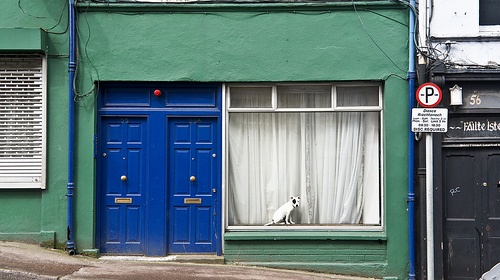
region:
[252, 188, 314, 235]
a dog with one brown eye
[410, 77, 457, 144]
a pair of traffic signs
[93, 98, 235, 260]
a pair of blue doors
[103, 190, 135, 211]
a gold mail slot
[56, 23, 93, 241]
a blue metal pole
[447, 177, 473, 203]
a small patch of grafiti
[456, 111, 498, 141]
a painted on sign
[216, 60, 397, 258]
a large square window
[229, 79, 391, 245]
a set of white curtains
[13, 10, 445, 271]
a dark green wall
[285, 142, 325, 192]
part of a window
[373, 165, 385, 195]
edge of a window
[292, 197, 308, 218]
part of a head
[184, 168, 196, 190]
part of a handle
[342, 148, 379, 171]
part of a handle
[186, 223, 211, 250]
part of a handle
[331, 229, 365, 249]
edge of a window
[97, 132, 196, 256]
the doors are blue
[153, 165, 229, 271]
the doors are blue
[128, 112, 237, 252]
the doors are blue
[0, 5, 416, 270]
a green building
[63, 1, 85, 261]
royal blue drain pipe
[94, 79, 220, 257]
two royal blue doors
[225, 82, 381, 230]
a large window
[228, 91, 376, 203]
window has white curtains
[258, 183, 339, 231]
a small black and white dog sitting in a window sill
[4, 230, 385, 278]
pavement in front of building is uneven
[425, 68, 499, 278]
black doors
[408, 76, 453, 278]
a sign on a pole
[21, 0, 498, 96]
electrical cords running in front of buildings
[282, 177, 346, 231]
white dog on window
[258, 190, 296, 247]
white dog on window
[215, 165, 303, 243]
white dog on window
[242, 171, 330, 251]
white dog on window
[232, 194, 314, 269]
white dog on window